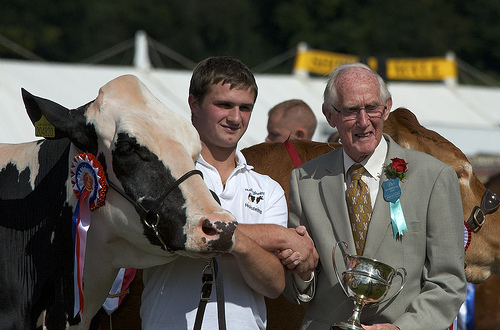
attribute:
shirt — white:
[137, 150, 287, 325]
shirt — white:
[130, 45, 293, 329]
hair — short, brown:
[188, 55, 258, 118]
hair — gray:
[316, 59, 343, 105]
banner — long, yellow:
[296, 47, 456, 84]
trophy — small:
[301, 220, 412, 299]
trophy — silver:
[328, 235, 411, 325]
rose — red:
[386, 153, 408, 181]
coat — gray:
[284, 141, 469, 328]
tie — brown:
[344, 161, 372, 256]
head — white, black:
[22, 72, 237, 270]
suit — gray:
[288, 130, 467, 328]